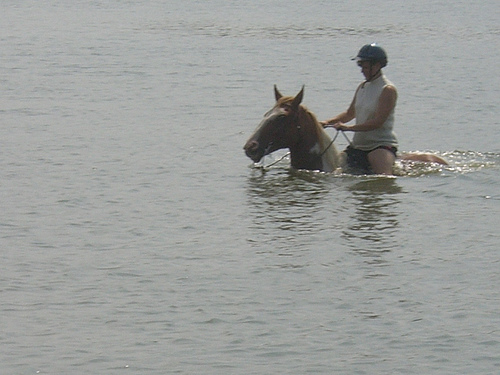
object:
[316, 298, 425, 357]
wave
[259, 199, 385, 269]
water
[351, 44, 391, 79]
head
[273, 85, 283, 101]
ear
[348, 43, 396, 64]
cap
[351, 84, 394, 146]
elbow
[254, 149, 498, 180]
ripples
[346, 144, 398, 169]
pant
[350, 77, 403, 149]
shirt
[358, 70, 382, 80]
chin strap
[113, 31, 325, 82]
water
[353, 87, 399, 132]
arm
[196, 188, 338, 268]
ripple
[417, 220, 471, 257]
wavy water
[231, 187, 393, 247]
water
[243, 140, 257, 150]
nose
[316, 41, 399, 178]
human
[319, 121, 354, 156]
halter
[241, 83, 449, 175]
horse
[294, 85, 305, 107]
ear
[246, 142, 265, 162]
mouth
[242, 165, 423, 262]
reflection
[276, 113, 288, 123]
eye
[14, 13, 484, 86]
background